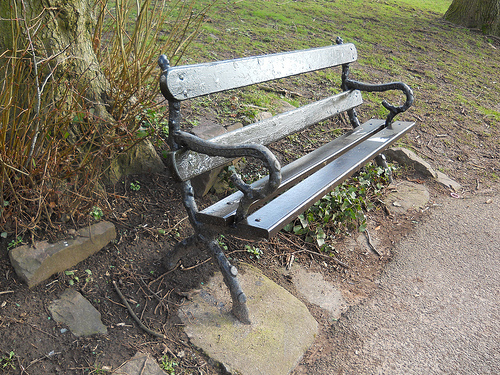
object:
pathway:
[384, 200, 500, 373]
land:
[92, 0, 497, 217]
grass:
[94, 2, 497, 202]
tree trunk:
[26, 83, 112, 201]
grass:
[354, 7, 497, 207]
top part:
[159, 45, 361, 98]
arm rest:
[173, 130, 282, 226]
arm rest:
[341, 79, 415, 127]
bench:
[157, 36, 418, 323]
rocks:
[286, 250, 351, 319]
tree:
[6, 1, 142, 152]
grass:
[1, 1, 208, 231]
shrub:
[285, 148, 394, 257]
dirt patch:
[0, 165, 336, 375]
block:
[177, 259, 320, 374]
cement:
[298, 196, 496, 375]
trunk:
[2, 51, 146, 221]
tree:
[2, 1, 162, 208]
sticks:
[73, 261, 214, 343]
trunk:
[441, 2, 498, 35]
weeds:
[293, 168, 406, 249]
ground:
[0, 0, 498, 372]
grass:
[201, 1, 314, 183]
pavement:
[323, 301, 500, 373]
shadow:
[347, 119, 405, 152]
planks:
[156, 42, 359, 102]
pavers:
[177, 259, 318, 374]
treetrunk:
[3, 5, 162, 179]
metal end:
[260, 146, 287, 185]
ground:
[0, 270, 198, 375]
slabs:
[181, 264, 321, 371]